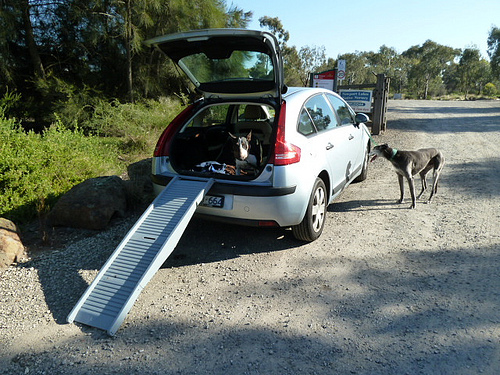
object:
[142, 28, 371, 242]
car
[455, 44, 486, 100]
trees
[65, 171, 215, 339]
ramp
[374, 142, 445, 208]
dog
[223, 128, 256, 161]
dog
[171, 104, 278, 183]
trunk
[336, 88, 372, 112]
signs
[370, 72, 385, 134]
post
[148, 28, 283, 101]
door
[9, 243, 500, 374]
shadow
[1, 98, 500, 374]
road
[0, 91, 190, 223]
grass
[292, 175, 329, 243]
tire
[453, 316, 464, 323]
gravel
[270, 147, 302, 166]
taillight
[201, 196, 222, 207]
license plate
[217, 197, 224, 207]
number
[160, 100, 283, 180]
hatch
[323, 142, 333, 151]
handle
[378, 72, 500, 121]
entrance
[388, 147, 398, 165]
collar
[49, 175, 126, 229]
rock